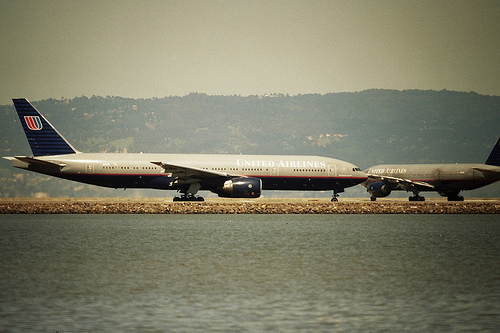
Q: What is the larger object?
A: United Airlines Plane.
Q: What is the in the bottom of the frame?
A: Water.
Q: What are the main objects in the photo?
A: Two Planes.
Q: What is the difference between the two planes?
A: One is smaller than the other.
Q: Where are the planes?
A: In the middle of the water.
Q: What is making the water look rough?
A: Ripples.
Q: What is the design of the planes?
A: Grey with White Writing and Blue Bottom.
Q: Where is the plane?
A: On the runway.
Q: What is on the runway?
A: Two jets.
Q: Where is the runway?
A: Past the water.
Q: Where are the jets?
A: Next to each other.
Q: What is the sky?
A: Overcast and grey.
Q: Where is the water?
A: In front of the planes.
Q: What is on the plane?
A: A red stripe.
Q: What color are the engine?
A: Blue.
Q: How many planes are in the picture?
A: Two.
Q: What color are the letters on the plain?
A: White.